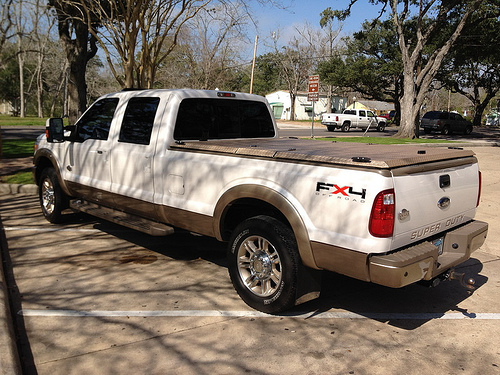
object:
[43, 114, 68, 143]
mirror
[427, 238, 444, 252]
license plate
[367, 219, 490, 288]
bumper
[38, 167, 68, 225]
front tire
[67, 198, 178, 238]
board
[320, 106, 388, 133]
truck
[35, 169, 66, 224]
wheel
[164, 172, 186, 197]
cover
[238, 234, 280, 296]
chrome rim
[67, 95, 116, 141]
window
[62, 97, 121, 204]
door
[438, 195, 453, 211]
ford emblem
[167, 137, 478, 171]
cover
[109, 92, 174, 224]
door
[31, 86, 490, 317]
truck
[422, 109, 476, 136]
jeep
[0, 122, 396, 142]
street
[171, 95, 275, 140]
window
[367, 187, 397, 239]
light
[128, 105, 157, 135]
tints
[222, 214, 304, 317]
wheel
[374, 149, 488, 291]
rear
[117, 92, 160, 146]
window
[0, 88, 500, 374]
parking lot